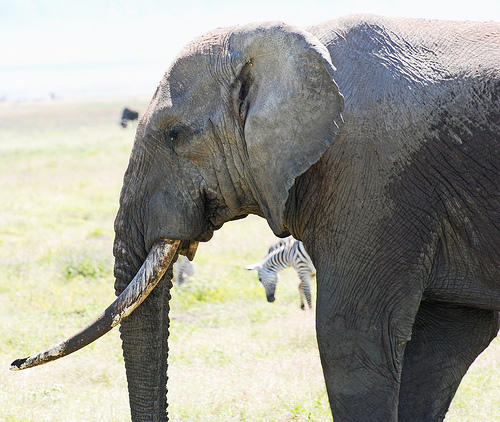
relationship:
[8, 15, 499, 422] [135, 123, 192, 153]
animal has eye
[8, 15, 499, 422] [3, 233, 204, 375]
animal has tusk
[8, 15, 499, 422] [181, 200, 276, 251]
animal has mouth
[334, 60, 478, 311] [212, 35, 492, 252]
wrinkles on skin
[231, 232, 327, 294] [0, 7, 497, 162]
animal in background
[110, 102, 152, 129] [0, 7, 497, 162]
animal in background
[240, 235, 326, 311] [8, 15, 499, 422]
animal behind animal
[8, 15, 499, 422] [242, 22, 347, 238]
animal has an ear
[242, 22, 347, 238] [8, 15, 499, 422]
ear of an animal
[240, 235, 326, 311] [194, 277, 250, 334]
animal eating grass